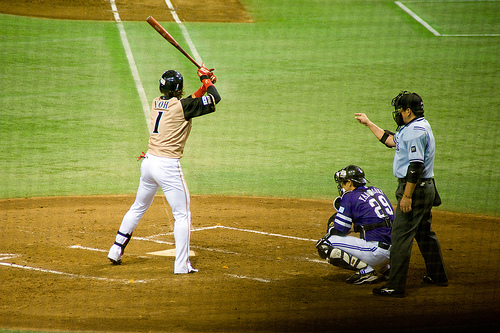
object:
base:
[135, 240, 207, 277]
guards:
[316, 237, 369, 271]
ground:
[435, 155, 484, 210]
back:
[144, 95, 194, 159]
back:
[343, 191, 399, 250]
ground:
[271, 241, 323, 283]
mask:
[335, 181, 343, 196]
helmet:
[333, 164, 371, 196]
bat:
[144, 15, 203, 69]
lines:
[0, 251, 119, 283]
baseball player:
[106, 62, 221, 274]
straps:
[117, 230, 130, 239]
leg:
[110, 160, 157, 251]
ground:
[439, 86, 491, 143]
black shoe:
[423, 274, 448, 286]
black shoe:
[372, 286, 407, 297]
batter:
[108, 64, 220, 271]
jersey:
[148, 93, 217, 159]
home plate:
[146, 248, 199, 258]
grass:
[284, 30, 346, 73]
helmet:
[159, 69, 183, 94]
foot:
[174, 263, 198, 273]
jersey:
[334, 185, 395, 245]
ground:
[7, 11, 92, 96]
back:
[413, 120, 434, 176]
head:
[394, 94, 419, 124]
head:
[338, 164, 361, 191]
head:
[160, 70, 184, 96]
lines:
[106, 0, 144, 90]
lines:
[395, 2, 500, 36]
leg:
[158, 175, 192, 264]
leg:
[416, 211, 444, 275]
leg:
[390, 199, 418, 287]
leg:
[321, 234, 373, 271]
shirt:
[393, 117, 436, 179]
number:
[369, 195, 394, 219]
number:
[152, 111, 164, 134]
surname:
[358, 187, 384, 202]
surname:
[154, 101, 169, 109]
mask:
[391, 97, 404, 126]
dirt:
[8, 190, 484, 320]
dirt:
[0, 1, 244, 22]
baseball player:
[315, 164, 396, 284]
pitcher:
[354, 90, 450, 297]